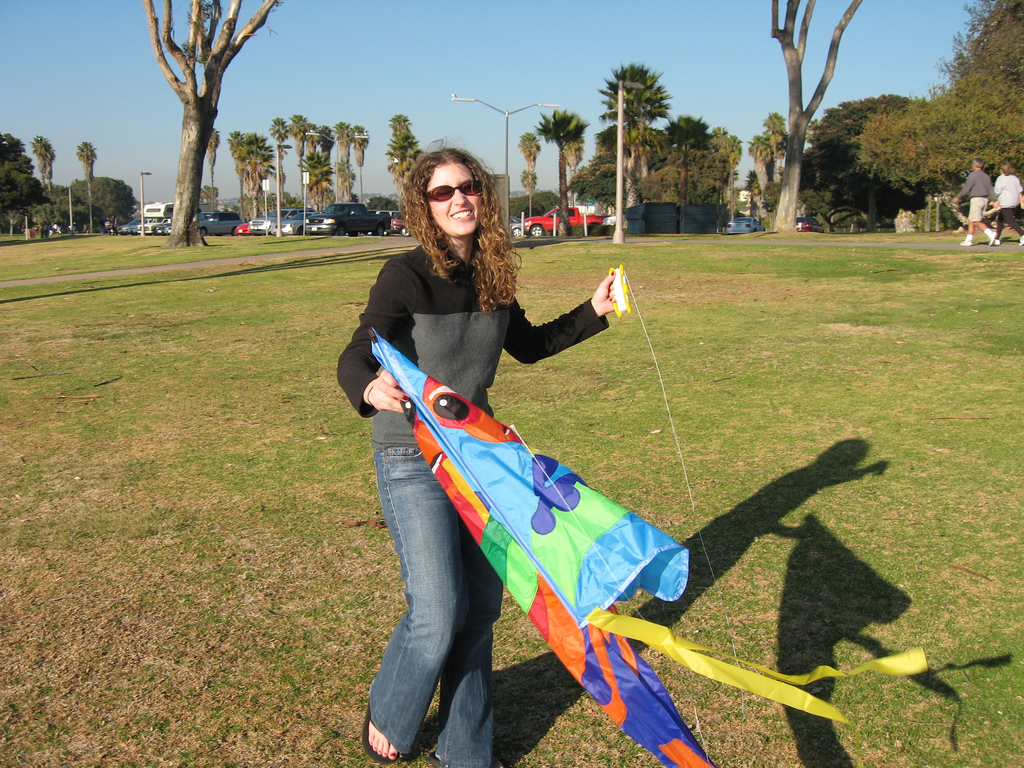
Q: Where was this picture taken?
A: In the field.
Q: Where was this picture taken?
A: In the field.